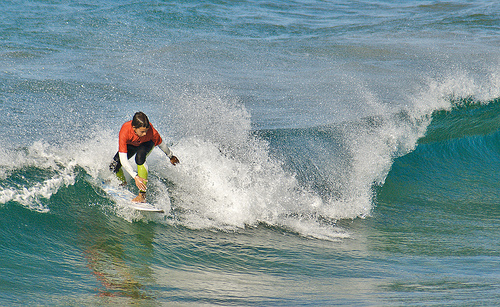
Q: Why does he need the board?
A: To stand on.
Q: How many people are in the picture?
A: One.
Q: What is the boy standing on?
A: A surfboard.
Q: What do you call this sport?
A: Surfboarding.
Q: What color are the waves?
A: White.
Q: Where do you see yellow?
A: On his leg.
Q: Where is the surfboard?
A: On the water.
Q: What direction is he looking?
A: Down.